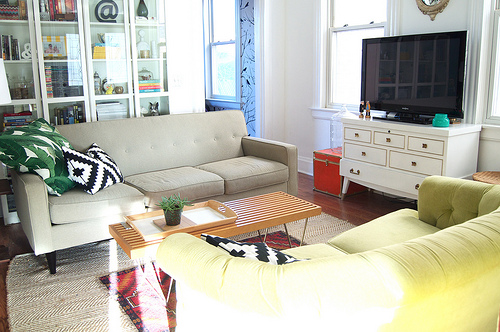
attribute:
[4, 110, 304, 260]
couch — light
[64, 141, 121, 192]
pillow — green, white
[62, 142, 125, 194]
pillow — black and white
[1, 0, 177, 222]
bookshelf — glass